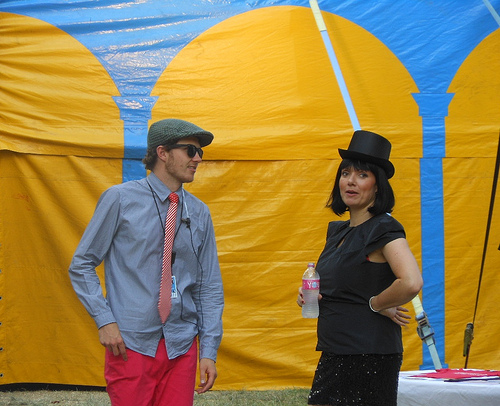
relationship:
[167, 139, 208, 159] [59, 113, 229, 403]
glasses worn by human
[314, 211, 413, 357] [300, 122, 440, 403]
shirt worn by human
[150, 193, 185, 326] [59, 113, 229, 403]
tie worn by human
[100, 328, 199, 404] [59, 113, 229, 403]
pants worn by human